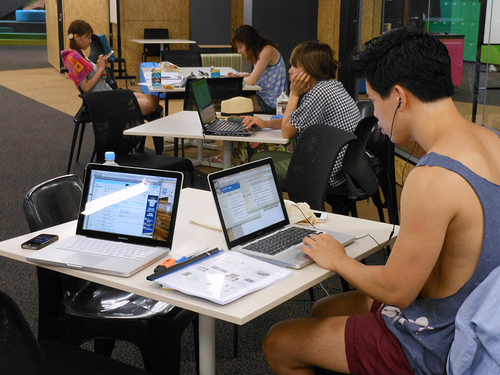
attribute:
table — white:
[1, 186, 401, 374]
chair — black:
[324, 116, 379, 217]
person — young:
[261, 26, 499, 374]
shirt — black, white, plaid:
[290, 78, 363, 187]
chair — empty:
[22, 172, 200, 374]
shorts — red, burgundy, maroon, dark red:
[290, 300, 344, 374]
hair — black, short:
[343, 24, 454, 104]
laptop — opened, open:
[207, 155, 356, 269]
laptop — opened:
[26, 162, 185, 280]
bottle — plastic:
[99, 151, 120, 166]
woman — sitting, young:
[60, 18, 160, 116]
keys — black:
[244, 226, 324, 255]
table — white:
[140, 66, 263, 95]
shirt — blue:
[379, 124, 499, 373]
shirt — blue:
[257, 48, 287, 108]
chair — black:
[79, 88, 197, 186]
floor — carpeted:
[1, 40, 499, 374]